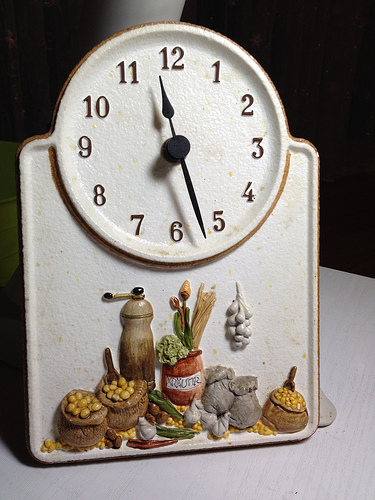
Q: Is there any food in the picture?
A: Yes, there is food.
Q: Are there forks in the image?
A: No, there are no forks.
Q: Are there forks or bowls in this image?
A: No, there are no forks or bowls.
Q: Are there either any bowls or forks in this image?
A: No, there are no forks or bowls.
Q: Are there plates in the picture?
A: No, there are no plates.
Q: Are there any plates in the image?
A: No, there are no plates.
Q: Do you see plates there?
A: No, there are no plates.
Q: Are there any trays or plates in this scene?
A: No, there are no plates or trays.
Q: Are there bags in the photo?
A: Yes, there is a bag.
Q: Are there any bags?
A: Yes, there is a bag.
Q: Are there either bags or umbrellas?
A: Yes, there is a bag.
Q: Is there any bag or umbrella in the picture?
A: Yes, there is a bag.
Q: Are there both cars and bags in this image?
A: No, there is a bag but no cars.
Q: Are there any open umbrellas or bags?
A: Yes, there is an open bag.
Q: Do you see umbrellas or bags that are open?
A: Yes, the bag is open.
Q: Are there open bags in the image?
A: Yes, there is an open bag.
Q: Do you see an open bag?
A: Yes, there is an open bag.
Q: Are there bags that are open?
A: Yes, there is a bag that is open.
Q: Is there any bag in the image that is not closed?
A: Yes, there is a open bag.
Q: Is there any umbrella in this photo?
A: No, there are no umbrellas.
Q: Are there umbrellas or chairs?
A: No, there are no umbrellas or chairs.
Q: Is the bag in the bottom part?
A: Yes, the bag is in the bottom of the image.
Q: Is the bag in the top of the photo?
A: No, the bag is in the bottom of the image.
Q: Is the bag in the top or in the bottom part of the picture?
A: The bag is in the bottom of the image.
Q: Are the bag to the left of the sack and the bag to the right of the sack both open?
A: Yes, both the bag and the bag are open.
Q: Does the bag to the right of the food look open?
A: Yes, the bag is open.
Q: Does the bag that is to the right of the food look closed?
A: No, the bag is open.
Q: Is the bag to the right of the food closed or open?
A: The bag is open.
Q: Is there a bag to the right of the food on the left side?
A: Yes, there is a bag to the right of the food.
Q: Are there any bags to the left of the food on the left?
A: No, the bag is to the right of the food.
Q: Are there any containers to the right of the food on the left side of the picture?
A: No, there is a bag to the right of the food.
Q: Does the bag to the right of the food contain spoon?
A: Yes, the bag contains spoon.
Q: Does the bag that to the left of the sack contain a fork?
A: No, the bag contains spoon.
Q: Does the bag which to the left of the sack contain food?
A: Yes, the bag contains food.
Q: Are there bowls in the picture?
A: No, there are no bowls.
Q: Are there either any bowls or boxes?
A: No, there are no bowls or boxes.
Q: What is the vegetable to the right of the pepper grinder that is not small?
A: The vegetable is garlic.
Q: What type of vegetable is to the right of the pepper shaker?
A: The vegetable is garlic.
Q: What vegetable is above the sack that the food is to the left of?
A: The vegetable is garlic.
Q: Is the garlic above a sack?
A: Yes, the garlic is above a sack.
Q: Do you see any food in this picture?
A: Yes, there is food.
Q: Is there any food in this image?
A: Yes, there is food.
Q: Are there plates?
A: No, there are no plates.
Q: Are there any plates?
A: No, there are no plates.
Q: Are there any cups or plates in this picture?
A: No, there are no plates or cups.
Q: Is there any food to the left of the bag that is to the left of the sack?
A: Yes, there is food to the left of the bag.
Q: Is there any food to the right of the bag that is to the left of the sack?
A: No, the food is to the left of the bag.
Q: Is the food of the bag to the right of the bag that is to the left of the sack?
A: No, the food is to the left of the bag.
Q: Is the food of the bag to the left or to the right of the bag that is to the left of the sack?
A: The food is to the left of the bag.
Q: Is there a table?
A: Yes, there is a table.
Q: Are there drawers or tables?
A: Yes, there is a table.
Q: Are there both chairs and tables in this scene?
A: No, there is a table but no chairs.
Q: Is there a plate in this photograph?
A: No, there are no plates.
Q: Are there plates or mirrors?
A: No, there are no plates or mirrors.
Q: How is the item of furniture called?
A: The piece of furniture is a table.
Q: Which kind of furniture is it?
A: The piece of furniture is a table.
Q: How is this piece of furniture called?
A: This is a table.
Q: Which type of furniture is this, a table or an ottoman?
A: This is a table.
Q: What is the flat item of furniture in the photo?
A: The piece of furniture is a table.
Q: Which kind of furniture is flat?
A: The furniture is a table.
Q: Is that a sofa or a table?
A: That is a table.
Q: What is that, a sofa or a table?
A: That is a table.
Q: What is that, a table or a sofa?
A: That is a table.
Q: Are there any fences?
A: No, there are no fences.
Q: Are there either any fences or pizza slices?
A: No, there are no fences or pizza slices.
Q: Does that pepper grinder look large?
A: Yes, the pepper grinder is large.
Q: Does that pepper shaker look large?
A: Yes, the pepper shaker is large.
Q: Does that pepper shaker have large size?
A: Yes, the pepper shaker is large.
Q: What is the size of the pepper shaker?
A: The pepper shaker is large.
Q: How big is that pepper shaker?
A: The pepper shaker is large.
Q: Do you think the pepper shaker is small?
A: No, the pepper shaker is large.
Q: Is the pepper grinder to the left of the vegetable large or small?
A: The pepper grinder is large.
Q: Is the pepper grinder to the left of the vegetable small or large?
A: The pepper grinder is large.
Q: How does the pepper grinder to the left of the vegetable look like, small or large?
A: The pepper grinder is large.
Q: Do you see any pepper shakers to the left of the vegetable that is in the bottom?
A: Yes, there is a pepper shaker to the left of the vegetable.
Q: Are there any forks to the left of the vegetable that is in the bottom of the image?
A: No, there is a pepper shaker to the left of the vegetable.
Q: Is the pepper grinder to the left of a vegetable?
A: Yes, the pepper grinder is to the left of a vegetable.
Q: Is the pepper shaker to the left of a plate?
A: No, the pepper shaker is to the left of a vegetable.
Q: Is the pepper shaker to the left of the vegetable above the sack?
A: Yes, the pepper shaker is to the left of the garlic.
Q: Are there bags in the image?
A: Yes, there is a bag.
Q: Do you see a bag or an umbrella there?
A: Yes, there is a bag.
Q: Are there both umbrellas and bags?
A: No, there is a bag but no umbrellas.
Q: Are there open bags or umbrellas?
A: Yes, there is an open bag.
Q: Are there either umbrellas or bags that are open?
A: Yes, the bag is open.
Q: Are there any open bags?
A: Yes, there is an open bag.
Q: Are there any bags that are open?
A: Yes, there is a bag that is open.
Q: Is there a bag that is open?
A: Yes, there is a bag that is open.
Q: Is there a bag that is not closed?
A: Yes, there is a open bag.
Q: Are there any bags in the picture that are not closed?
A: Yes, there is a open bag.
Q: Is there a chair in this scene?
A: No, there are no chairs.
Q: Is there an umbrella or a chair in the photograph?
A: No, there are no chairs or umbrellas.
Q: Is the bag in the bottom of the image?
A: Yes, the bag is in the bottom of the image.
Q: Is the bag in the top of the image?
A: No, the bag is in the bottom of the image.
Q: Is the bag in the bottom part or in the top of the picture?
A: The bag is in the bottom of the image.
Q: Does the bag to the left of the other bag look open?
A: Yes, the bag is open.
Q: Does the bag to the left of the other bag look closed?
A: No, the bag is open.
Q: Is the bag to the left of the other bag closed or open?
A: The bag is open.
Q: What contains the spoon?
A: The bag contains spoon.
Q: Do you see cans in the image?
A: No, there are no cans.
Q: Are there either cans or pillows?
A: No, there are no cans or pillows.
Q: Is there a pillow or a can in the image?
A: No, there are no cans or pillows.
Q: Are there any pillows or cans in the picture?
A: No, there are no cans or pillows.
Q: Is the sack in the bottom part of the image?
A: Yes, the sack is in the bottom of the image.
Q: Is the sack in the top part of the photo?
A: No, the sack is in the bottom of the image.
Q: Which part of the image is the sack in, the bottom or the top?
A: The sack is in the bottom of the image.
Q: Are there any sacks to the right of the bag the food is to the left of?
A: Yes, there is a sack to the right of the bag.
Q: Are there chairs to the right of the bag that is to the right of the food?
A: No, there is a sack to the right of the bag.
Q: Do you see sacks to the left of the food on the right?
A: Yes, there is a sack to the left of the food.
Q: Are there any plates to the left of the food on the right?
A: No, there is a sack to the left of the food.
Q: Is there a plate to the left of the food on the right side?
A: No, there is a sack to the left of the food.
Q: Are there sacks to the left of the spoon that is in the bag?
A: Yes, there is a sack to the left of the spoon.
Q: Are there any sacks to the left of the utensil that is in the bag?
A: Yes, there is a sack to the left of the spoon.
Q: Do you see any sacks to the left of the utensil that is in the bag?
A: Yes, there is a sack to the left of the spoon.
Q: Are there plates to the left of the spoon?
A: No, there is a sack to the left of the spoon.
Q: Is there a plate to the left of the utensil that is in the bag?
A: No, there is a sack to the left of the spoon.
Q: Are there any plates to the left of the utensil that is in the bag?
A: No, there is a sack to the left of the spoon.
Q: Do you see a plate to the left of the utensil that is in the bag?
A: No, there is a sack to the left of the spoon.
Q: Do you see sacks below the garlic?
A: Yes, there is a sack below the garlic.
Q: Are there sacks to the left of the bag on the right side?
A: Yes, there is a sack to the left of the bag.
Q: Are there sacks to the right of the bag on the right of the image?
A: No, the sack is to the left of the bag.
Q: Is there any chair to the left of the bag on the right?
A: No, there is a sack to the left of the bag.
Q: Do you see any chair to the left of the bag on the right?
A: No, there is a sack to the left of the bag.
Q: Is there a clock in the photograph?
A: Yes, there is a clock.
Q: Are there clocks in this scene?
A: Yes, there is a clock.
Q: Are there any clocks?
A: Yes, there is a clock.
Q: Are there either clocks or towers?
A: Yes, there is a clock.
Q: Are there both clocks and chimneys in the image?
A: No, there is a clock but no chimneys.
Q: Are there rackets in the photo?
A: No, there are no rackets.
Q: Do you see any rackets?
A: No, there are no rackets.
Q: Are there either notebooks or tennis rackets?
A: No, there are no tennis rackets or notebooks.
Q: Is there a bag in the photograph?
A: Yes, there is a bag.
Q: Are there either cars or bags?
A: Yes, there is a bag.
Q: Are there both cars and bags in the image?
A: No, there is a bag but no cars.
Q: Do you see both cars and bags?
A: No, there is a bag but no cars.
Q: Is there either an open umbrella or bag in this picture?
A: Yes, there is an open bag.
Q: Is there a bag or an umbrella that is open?
A: Yes, the bag is open.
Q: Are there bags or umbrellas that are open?
A: Yes, the bag is open.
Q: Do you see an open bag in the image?
A: Yes, there is an open bag.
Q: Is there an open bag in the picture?
A: Yes, there is an open bag.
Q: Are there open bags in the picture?
A: Yes, there is an open bag.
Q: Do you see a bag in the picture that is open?
A: Yes, there is a bag that is open.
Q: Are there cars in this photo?
A: No, there are no cars.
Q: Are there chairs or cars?
A: No, there are no cars or chairs.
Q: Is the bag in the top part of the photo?
A: No, the bag is in the bottom of the image.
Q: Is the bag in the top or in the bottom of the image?
A: The bag is in the bottom of the image.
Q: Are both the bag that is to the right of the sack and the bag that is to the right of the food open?
A: Yes, both the bag and the bag are open.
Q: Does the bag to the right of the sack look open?
A: Yes, the bag is open.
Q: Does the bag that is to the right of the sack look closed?
A: No, the bag is open.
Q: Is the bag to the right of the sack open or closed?
A: The bag is open.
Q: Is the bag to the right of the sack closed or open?
A: The bag is open.